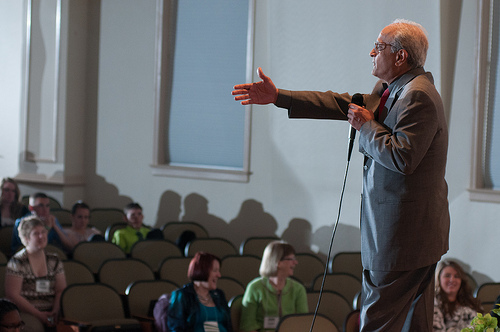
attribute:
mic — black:
[339, 91, 369, 167]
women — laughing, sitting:
[187, 248, 300, 295]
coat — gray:
[360, 96, 437, 267]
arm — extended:
[229, 60, 354, 133]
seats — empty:
[82, 240, 184, 274]